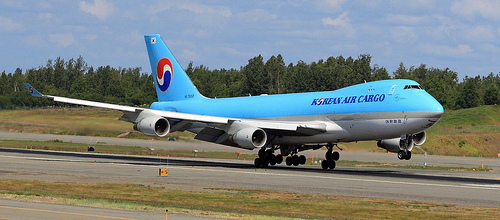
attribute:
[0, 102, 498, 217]
grass — green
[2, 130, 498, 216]
tarmac — grey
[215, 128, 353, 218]
gear — landing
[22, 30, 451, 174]
plane — blue, white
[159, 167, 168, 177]
sign — yellow and black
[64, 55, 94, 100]
tree — green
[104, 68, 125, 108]
tree — green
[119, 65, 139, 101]
tree — green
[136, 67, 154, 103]
tree — green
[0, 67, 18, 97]
tree — green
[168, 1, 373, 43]
skies — cloudy, blue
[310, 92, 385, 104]
lettering — blue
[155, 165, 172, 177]
orange light — small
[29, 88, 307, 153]
wing — thin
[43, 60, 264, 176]
wing — white